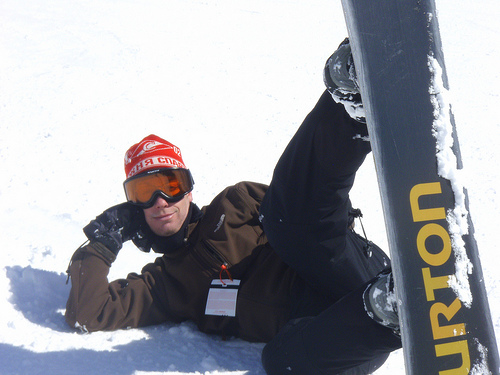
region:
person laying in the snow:
[65, 34, 402, 374]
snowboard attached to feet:
[341, 1, 499, 373]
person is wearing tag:
[199, 260, 241, 317]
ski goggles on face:
[124, 168, 194, 203]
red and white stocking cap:
[124, 133, 187, 179]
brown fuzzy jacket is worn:
[66, 183, 311, 341]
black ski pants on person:
[259, 88, 401, 373]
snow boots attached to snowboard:
[322, 36, 419, 333]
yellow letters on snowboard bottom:
[406, 176, 471, 373]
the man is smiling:
[123, 138, 192, 239]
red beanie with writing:
[113, 120, 193, 184]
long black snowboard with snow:
[335, 2, 499, 370]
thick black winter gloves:
[57, 187, 158, 262]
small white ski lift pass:
[174, 250, 261, 342]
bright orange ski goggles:
[103, 155, 203, 217]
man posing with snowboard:
[48, 7, 498, 366]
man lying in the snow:
[52, 115, 360, 373]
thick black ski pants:
[240, 23, 415, 373]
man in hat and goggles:
[101, 117, 210, 249]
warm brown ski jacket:
[51, 170, 321, 347]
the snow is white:
[73, 339, 90, 359]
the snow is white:
[119, 337, 129, 351]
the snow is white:
[72, 157, 96, 184]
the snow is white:
[137, 354, 153, 368]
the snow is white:
[147, 358, 162, 367]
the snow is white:
[156, 344, 176, 371]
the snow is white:
[129, 358, 141, 368]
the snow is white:
[120, 348, 146, 371]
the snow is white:
[113, 360, 128, 374]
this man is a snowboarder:
[28, 1, 490, 373]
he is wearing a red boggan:
[101, 97, 201, 263]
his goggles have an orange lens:
[106, 170, 196, 217]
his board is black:
[376, 12, 498, 349]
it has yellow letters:
[333, 30, 490, 372]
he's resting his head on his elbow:
[48, 7, 493, 371]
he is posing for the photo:
[64, 0, 495, 370]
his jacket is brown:
[45, 135, 291, 335]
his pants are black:
[185, 35, 427, 369]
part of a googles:
[141, 160, 174, 189]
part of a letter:
[419, 296, 450, 329]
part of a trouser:
[321, 320, 371, 361]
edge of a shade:
[108, 333, 151, 348]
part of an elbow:
[57, 299, 97, 334]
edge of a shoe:
[352, 287, 391, 327]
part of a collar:
[180, 220, 203, 240]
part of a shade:
[33, 329, 80, 365]